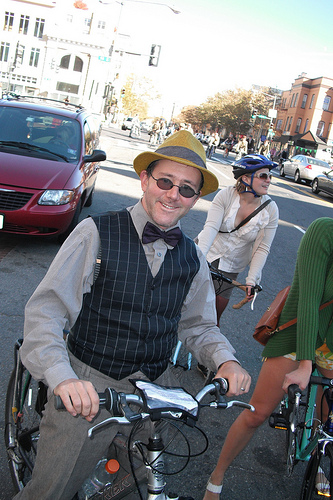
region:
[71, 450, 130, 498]
A water bottle with orange lid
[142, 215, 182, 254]
A brown bow tie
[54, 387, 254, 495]
A grey mountain bike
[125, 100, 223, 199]
A yellow hut with grey band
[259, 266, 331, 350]
A brown slim bag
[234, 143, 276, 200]
A blue and black Helmet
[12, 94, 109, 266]
A maroon car on halt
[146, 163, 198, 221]
A face of a man smilling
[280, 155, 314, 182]
A white car parked on the road side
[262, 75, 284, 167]
A white street light pole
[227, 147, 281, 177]
A blue bicycle helmet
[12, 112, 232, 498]
Man riding a bicycle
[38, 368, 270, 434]
Handlebars on a bicycle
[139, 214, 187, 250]
A black bowtie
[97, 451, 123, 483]
Orange cap on a bottle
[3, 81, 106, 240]
Red car in the street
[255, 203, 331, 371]
A green sweater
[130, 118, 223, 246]
Man wearing a hat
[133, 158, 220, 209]
Man is wearing sunglasses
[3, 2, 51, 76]
Windows on a building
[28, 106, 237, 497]
A man on a bike in a yellow hat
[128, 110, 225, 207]
a yellow hat with gray trim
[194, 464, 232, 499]
a white sandle on her foot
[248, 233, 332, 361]
She wears a long sleeved green sweater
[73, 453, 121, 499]
a water bottle with orange cap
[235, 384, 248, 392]
a wedding ring on the man's hand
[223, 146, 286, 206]
a blue and black helmet on the woman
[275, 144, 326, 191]
a silver car on the road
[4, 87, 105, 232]
a red minivan behind the bikes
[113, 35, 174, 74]
A traffic light facing the other direction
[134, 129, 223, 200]
a man's yellow hat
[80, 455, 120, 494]
a plastic water bottle with an orange top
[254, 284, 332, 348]
a brown shoulder bag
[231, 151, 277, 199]
a blue helmet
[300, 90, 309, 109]
a window of a building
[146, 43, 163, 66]
a black street light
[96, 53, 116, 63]
a green and white street sign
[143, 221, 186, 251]
a man's black bow tie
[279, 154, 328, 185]
a large gray car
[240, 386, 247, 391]
a man's wedding band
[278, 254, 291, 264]
Small part of a black street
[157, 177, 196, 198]
Shades of the man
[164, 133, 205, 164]
Golden and black hat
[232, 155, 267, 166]
Blue and black helmet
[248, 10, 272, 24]
A bright blue sky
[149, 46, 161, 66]
Black back of street light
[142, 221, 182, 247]
Black bow tie of man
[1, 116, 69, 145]
Front window of the van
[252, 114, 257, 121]
Green light of the street light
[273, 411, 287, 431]
Black and yellow right pedal of the female's bike